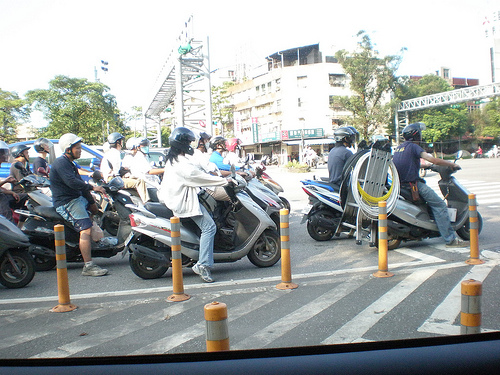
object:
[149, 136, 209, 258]
woman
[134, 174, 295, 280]
motorcycle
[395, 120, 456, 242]
man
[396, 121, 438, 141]
helmet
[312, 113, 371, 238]
motorcyclist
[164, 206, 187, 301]
pole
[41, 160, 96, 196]
sweatshirt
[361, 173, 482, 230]
motorcycle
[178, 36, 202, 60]
rag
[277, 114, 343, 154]
sign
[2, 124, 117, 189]
automobile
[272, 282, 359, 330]
line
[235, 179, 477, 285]
street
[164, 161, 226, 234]
jacket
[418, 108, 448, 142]
bush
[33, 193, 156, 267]
scooter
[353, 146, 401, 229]
ladder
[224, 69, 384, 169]
building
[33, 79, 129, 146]
tree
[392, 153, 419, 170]
shirt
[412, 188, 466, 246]
jeans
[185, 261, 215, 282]
sneakers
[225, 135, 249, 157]
helmet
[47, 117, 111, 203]
people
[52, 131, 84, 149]
helmet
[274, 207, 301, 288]
pylon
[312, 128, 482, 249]
motorcycle